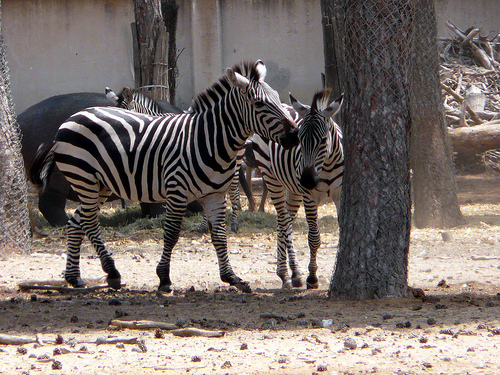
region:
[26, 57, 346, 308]
Two zebras next to each other.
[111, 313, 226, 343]
Two sticks on the ground.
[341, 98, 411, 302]
A strange pattern on the tree trunk.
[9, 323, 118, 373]
Rocks and sticks on the ground.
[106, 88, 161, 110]
Half of a zebra head.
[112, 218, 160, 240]
Dry grass on the ground.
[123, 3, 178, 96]
A tree trunk in the background.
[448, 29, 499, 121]
A pile of sticks and debris.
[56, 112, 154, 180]
Black and white stripes on the rear of the zebra.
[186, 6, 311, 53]
A dilapidated wall in the zebra pen.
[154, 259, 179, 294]
the zebra's right front hoof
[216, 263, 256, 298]
the zebra's left front hoof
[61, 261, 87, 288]
the zebra's left back hoof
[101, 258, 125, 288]
the zebra's right back hoof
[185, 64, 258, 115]
the zebra's white and black mane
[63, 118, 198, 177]
the zebra's white and black stripes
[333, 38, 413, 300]
brown trunk of a tree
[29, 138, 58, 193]
the zebra's white and black tail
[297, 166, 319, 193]
the zebra's black nose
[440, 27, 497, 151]
pieces of tree branches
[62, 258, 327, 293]
SEVEN BLACK HOOVES OF ZEBRAS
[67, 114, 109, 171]
FOUR BLACK AND WHITE STRIPES OF A ZEBRA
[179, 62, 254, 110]
BLACK AND WHITE MANE OF A ZEBRA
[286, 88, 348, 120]
TWO EARS AND MANE OF A ZEBRA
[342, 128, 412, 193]
ROUGH GREY AND BLACK BARK OF A TREE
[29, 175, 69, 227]
LEG OF ANIMAL STANDING BEHIND A ZEBRA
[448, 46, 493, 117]
PILE OF SCRAP WOOD AND TREE STICKS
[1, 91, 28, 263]
ROLL OF CHAIN LINK FENCING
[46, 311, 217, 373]
TREE DROPPINGS AND PIECES OF STICKS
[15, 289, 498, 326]
SHADOW UNDER A TREE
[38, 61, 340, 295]
two zebras standing near a tree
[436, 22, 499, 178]
pile of wood in an animal enclosure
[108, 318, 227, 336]
sticks lying on dirt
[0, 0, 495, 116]
concrete wall in animal enclosure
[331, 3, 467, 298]
trees standing in animal enclosure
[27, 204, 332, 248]
grass growing in animal enclosure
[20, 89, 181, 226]
black animal behind zebras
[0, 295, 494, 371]
rocks on ground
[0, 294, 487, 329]
shadow appearing on dirt ground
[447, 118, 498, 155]
log laying on ground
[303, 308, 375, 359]
rocks on the ground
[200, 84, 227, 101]
hair on the zebra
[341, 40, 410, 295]
a tree trunk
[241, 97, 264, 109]
eye on the zebra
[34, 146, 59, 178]
the zebras tail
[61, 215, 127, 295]
the back legs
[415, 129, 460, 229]
the tree trunk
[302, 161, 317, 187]
a black nose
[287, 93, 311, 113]
ears of the zebra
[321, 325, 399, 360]
rocks on the ground